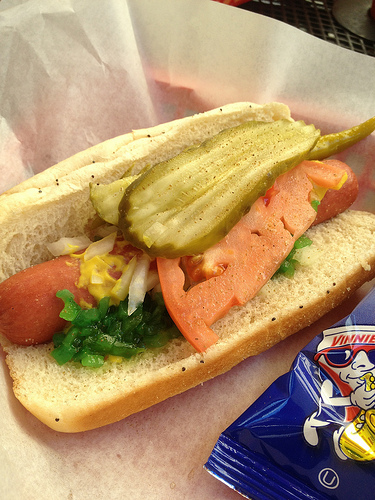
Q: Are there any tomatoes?
A: Yes, there is a tomato.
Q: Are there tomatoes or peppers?
A: Yes, there is a tomato.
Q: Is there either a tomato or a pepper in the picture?
A: Yes, there is a tomato.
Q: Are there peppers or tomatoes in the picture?
A: Yes, there is a tomato.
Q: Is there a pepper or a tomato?
A: Yes, there is a tomato.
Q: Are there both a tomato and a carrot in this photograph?
A: No, there is a tomato but no carrots.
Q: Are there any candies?
A: No, there are no candies.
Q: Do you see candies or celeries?
A: No, there are no candies or celeries.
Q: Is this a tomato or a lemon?
A: This is a tomato.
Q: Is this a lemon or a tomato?
A: This is a tomato.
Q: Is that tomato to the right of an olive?
A: No, the tomato is to the right of an onion.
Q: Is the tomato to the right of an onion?
A: Yes, the tomato is to the right of an onion.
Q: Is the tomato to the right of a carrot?
A: No, the tomato is to the right of an onion.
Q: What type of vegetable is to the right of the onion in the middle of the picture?
A: The vegetable is a tomato.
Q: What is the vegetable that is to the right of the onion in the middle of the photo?
A: The vegetable is a tomato.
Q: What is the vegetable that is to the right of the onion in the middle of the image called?
A: The vegetable is a tomato.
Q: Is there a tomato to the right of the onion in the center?
A: Yes, there is a tomato to the right of the onion.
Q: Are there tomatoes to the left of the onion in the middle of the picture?
A: No, the tomato is to the right of the onion.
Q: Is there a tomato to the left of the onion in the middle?
A: No, the tomato is to the right of the onion.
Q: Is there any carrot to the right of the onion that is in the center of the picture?
A: No, there is a tomato to the right of the onion.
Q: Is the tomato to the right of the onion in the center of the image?
A: Yes, the tomato is to the right of the onion.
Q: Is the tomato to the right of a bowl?
A: No, the tomato is to the right of the onion.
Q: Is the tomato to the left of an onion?
A: No, the tomato is to the right of an onion.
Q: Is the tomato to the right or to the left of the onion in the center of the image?
A: The tomato is to the right of the onion.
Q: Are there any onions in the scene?
A: Yes, there is an onion.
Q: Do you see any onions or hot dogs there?
A: Yes, there is an onion.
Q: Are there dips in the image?
A: No, there are no dips.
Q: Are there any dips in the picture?
A: No, there are no dips.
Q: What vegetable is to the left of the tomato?
A: The vegetable is an onion.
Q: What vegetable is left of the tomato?
A: The vegetable is an onion.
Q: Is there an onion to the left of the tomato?
A: Yes, there is an onion to the left of the tomato.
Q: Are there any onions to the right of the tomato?
A: No, the onion is to the left of the tomato.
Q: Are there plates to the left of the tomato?
A: No, there is an onion to the left of the tomato.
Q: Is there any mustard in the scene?
A: Yes, there is mustard.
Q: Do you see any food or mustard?
A: Yes, there is mustard.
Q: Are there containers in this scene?
A: No, there are no containers.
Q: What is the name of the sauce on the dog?
A: The sauce is mustard.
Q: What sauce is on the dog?
A: The sauce is mustard.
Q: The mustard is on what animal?
A: The mustard is on the dog.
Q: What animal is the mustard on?
A: The mustard is on the dog.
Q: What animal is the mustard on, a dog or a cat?
A: The mustard is on a dog.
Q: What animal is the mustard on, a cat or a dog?
A: The mustard is on a dog.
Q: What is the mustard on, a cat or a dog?
A: The mustard is on a dog.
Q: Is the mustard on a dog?
A: Yes, the mustard is on a dog.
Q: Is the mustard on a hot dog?
A: No, the mustard is on a dog.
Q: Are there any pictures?
A: No, there are no pictures.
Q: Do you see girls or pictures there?
A: No, there are no pictures or girls.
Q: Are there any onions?
A: Yes, there is an onion.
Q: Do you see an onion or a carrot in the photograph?
A: Yes, there is an onion.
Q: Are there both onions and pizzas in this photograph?
A: No, there is an onion but no pizzas.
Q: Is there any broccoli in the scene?
A: No, there is no broccoli.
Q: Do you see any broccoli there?
A: No, there is no broccoli.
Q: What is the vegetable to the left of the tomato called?
A: The vegetable is an onion.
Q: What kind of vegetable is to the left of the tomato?
A: The vegetable is an onion.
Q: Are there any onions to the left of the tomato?
A: Yes, there is an onion to the left of the tomato.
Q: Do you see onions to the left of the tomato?
A: Yes, there is an onion to the left of the tomato.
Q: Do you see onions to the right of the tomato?
A: No, the onion is to the left of the tomato.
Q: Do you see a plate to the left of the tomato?
A: No, there is an onion to the left of the tomato.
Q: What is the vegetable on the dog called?
A: The vegetable is an onion.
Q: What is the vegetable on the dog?
A: The vegetable is an onion.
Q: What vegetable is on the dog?
A: The vegetable is an onion.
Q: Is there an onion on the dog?
A: Yes, there is an onion on the dog.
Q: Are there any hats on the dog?
A: No, there is an onion on the dog.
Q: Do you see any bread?
A: Yes, there is a bread.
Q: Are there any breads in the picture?
A: Yes, there is a bread.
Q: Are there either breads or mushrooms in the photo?
A: Yes, there is a bread.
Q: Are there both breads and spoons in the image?
A: No, there is a bread but no spoons.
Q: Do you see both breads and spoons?
A: No, there is a bread but no spoons.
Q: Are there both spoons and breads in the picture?
A: No, there is a bread but no spoons.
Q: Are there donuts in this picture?
A: No, there are no donuts.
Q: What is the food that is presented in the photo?
A: The food is a bread.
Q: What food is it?
A: The food is a bread.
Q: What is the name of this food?
A: That is a bread.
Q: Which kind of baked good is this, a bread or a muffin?
A: That is a bread.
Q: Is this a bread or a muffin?
A: This is a bread.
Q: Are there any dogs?
A: Yes, there is a dog.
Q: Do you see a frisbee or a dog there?
A: Yes, there is a dog.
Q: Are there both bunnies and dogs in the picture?
A: No, there is a dog but no bunnies.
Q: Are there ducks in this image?
A: No, there are no ducks.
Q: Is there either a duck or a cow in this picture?
A: No, there are no ducks or cows.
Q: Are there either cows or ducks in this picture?
A: No, there are no ducks or cows.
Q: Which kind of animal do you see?
A: The animal is a dog.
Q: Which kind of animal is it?
A: The animal is a dog.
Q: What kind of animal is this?
A: This is a dog.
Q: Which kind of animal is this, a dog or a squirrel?
A: This is a dog.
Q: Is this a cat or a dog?
A: This is a dog.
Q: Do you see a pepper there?
A: Yes, there is a pepper.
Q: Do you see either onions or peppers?
A: Yes, there is a pepper.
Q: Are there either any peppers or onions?
A: Yes, there is a pepper.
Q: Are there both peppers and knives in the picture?
A: No, there is a pepper but no knives.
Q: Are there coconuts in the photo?
A: No, there are no coconuts.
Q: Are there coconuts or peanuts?
A: No, there are no coconuts or peanuts.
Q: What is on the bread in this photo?
A: The pepper is on the bread.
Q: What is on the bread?
A: The pepper is on the bread.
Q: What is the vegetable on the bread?
A: The vegetable is a pepper.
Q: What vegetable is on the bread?
A: The vegetable is a pepper.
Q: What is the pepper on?
A: The pepper is on the bread.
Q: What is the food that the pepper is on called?
A: The food is a bread.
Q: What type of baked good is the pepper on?
A: The pepper is on the bread.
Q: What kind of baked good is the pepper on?
A: The pepper is on the bread.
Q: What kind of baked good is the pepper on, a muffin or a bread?
A: The pepper is on a bread.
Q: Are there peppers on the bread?
A: Yes, there is a pepper on the bread.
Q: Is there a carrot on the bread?
A: No, there is a pepper on the bread.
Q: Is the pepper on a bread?
A: Yes, the pepper is on a bread.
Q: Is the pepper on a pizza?
A: No, the pepper is on a bread.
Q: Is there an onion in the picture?
A: Yes, there is an onion.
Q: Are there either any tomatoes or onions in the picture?
A: Yes, there is an onion.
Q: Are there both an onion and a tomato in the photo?
A: Yes, there are both an onion and a tomato.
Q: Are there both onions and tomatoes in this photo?
A: Yes, there are both an onion and a tomato.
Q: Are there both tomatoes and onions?
A: Yes, there are both an onion and a tomato.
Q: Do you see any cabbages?
A: No, there are no cabbages.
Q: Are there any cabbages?
A: No, there are no cabbages.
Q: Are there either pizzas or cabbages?
A: No, there are no cabbages or pizzas.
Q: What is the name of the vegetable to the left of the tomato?
A: The vegetable is an onion.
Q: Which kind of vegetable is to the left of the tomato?
A: The vegetable is an onion.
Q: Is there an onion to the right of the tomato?
A: No, the onion is to the left of the tomato.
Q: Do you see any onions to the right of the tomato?
A: No, the onion is to the left of the tomato.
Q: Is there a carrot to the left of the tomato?
A: No, there is an onion to the left of the tomato.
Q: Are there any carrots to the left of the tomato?
A: No, there is an onion to the left of the tomato.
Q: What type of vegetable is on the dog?
A: The vegetable is an onion.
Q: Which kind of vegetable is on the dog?
A: The vegetable is an onion.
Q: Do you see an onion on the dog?
A: Yes, there is an onion on the dog.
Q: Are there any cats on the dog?
A: No, there is an onion on the dog.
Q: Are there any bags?
A: Yes, there is a bag.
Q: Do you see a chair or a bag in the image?
A: Yes, there is a bag.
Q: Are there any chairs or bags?
A: Yes, there is a bag.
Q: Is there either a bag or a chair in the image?
A: Yes, there is a bag.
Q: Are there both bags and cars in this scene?
A: No, there is a bag but no cars.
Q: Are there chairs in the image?
A: No, there are no chairs.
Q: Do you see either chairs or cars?
A: No, there are no chairs or cars.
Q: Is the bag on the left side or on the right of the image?
A: The bag is on the right of the image.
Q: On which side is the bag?
A: The bag is on the right of the image.